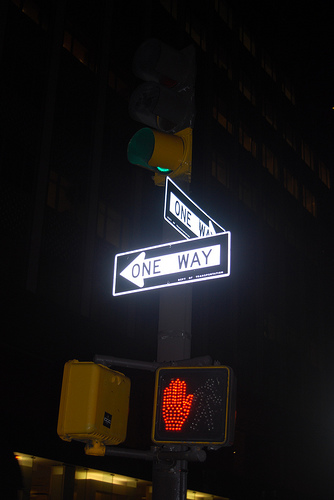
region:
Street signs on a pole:
[56, 18, 267, 497]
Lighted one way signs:
[90, 182, 252, 312]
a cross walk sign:
[145, 350, 251, 454]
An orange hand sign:
[156, 375, 194, 441]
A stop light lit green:
[127, 29, 195, 185]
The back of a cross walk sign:
[48, 359, 137, 466]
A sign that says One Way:
[117, 241, 228, 282]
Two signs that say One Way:
[117, 175, 247, 295]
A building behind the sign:
[215, 9, 331, 389]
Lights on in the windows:
[215, 52, 331, 238]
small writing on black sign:
[168, 269, 241, 279]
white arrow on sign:
[118, 250, 221, 279]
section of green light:
[149, 163, 176, 172]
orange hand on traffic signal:
[153, 370, 200, 432]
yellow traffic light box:
[47, 356, 140, 453]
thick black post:
[138, 289, 212, 341]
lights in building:
[79, 462, 134, 483]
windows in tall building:
[225, 113, 310, 190]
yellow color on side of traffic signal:
[160, 135, 190, 165]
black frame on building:
[57, 456, 83, 489]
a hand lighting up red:
[155, 371, 192, 436]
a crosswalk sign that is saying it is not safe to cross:
[155, 365, 225, 444]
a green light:
[118, 127, 199, 177]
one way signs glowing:
[109, 174, 238, 300]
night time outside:
[12, 3, 325, 490]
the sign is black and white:
[99, 186, 237, 297]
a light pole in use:
[55, 43, 235, 491]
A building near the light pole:
[9, 19, 330, 491]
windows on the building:
[203, 44, 326, 201]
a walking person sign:
[188, 375, 228, 438]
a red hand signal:
[160, 377, 195, 434]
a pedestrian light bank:
[147, 361, 235, 449]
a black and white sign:
[108, 229, 234, 297]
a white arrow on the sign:
[117, 241, 223, 288]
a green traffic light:
[125, 128, 188, 174]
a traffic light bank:
[120, 34, 203, 189]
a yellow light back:
[53, 353, 138, 459]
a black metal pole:
[150, 179, 196, 498]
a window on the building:
[11, 448, 63, 498]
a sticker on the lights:
[99, 408, 115, 429]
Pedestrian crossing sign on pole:
[144, 342, 244, 451]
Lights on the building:
[23, 452, 98, 498]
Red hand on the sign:
[160, 367, 203, 448]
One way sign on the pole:
[114, 231, 252, 294]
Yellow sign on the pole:
[48, 351, 136, 445]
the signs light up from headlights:
[98, 199, 264, 313]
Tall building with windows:
[209, 47, 331, 190]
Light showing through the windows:
[203, 115, 301, 179]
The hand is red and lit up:
[161, 373, 196, 435]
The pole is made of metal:
[150, 291, 216, 356]